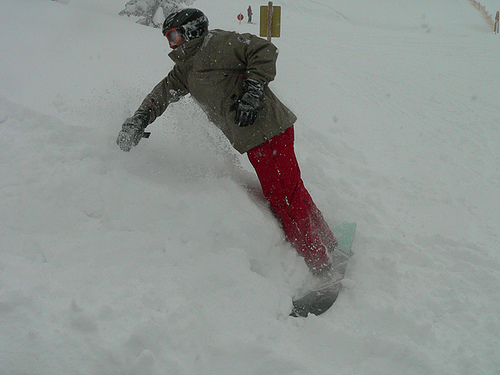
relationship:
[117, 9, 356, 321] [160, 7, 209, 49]
person wearing head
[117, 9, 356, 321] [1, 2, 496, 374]
person going down hill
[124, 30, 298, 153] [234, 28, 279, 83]
jacket has sleeve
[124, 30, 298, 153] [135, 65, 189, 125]
jacket has sleeve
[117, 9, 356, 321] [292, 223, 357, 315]
person on snowboard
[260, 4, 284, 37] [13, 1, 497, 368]
sign on trail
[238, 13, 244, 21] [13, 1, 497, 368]
sign on trail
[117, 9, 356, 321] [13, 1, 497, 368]
person on trail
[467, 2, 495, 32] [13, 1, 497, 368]
fence lining trail